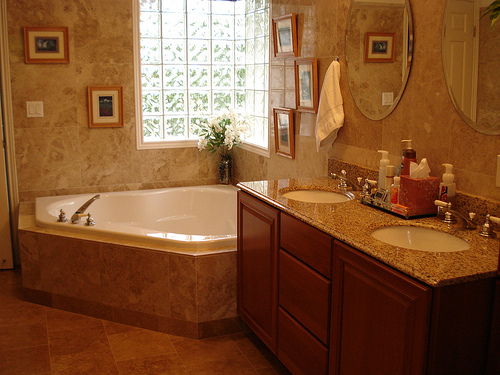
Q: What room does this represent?
A: It represents the bathroom.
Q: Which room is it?
A: It is a bathroom.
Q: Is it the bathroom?
A: Yes, it is the bathroom.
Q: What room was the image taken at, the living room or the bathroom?
A: It was taken at the bathroom.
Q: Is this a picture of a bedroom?
A: No, the picture is showing a bathroom.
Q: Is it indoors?
A: Yes, it is indoors.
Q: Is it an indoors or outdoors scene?
A: It is indoors.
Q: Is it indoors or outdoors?
A: It is indoors.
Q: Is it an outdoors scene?
A: No, it is indoors.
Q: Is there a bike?
A: No, there are no bikes.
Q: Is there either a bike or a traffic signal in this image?
A: No, there are no bikes or traffic lights.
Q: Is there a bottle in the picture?
A: Yes, there is a bottle.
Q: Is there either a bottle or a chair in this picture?
A: Yes, there is a bottle.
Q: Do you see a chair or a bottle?
A: Yes, there is a bottle.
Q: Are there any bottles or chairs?
A: Yes, there is a bottle.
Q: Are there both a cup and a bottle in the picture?
A: No, there is a bottle but no cups.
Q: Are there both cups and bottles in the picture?
A: No, there is a bottle but no cups.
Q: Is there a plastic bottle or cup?
A: Yes, there is a plastic bottle.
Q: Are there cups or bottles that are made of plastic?
A: Yes, the bottle is made of plastic.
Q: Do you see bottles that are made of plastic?
A: Yes, there is a bottle that is made of plastic.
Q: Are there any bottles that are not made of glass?
A: Yes, there is a bottle that is made of plastic.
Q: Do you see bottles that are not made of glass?
A: Yes, there is a bottle that is made of plastic.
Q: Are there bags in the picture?
A: No, there are no bags.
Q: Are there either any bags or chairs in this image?
A: No, there are no bags or chairs.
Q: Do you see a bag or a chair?
A: No, there are no bags or chairs.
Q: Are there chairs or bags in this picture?
A: No, there are no bags or chairs.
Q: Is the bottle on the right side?
A: Yes, the bottle is on the right of the image.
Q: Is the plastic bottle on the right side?
A: Yes, the bottle is on the right of the image.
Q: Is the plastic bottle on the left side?
A: No, the bottle is on the right of the image.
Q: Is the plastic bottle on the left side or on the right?
A: The bottle is on the right of the image.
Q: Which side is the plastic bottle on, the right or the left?
A: The bottle is on the right of the image.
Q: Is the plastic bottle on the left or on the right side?
A: The bottle is on the right of the image.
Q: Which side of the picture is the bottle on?
A: The bottle is on the right of the image.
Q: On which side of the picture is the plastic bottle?
A: The bottle is on the right of the image.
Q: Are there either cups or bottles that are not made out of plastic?
A: No, there is a bottle but it is made of plastic.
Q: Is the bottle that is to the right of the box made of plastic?
A: Yes, the bottle is made of plastic.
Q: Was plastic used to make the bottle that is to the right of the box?
A: Yes, the bottle is made of plastic.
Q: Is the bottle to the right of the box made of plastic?
A: Yes, the bottle is made of plastic.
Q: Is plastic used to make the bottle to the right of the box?
A: Yes, the bottle is made of plastic.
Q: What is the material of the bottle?
A: The bottle is made of plastic.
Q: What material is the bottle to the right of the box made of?
A: The bottle is made of plastic.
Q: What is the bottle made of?
A: The bottle is made of plastic.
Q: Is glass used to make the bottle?
A: No, the bottle is made of plastic.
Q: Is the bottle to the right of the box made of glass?
A: No, the bottle is made of plastic.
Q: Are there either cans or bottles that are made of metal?
A: No, there is a bottle but it is made of plastic.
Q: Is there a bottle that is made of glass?
A: No, there is a bottle but it is made of plastic.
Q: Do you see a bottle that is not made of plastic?
A: No, there is a bottle but it is made of plastic.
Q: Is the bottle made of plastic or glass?
A: The bottle is made of plastic.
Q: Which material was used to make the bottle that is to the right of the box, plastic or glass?
A: The bottle is made of plastic.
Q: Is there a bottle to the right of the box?
A: Yes, there is a bottle to the right of the box.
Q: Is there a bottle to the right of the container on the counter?
A: Yes, there is a bottle to the right of the box.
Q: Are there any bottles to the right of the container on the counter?
A: Yes, there is a bottle to the right of the box.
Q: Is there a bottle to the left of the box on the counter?
A: No, the bottle is to the right of the box.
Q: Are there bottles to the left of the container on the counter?
A: No, the bottle is to the right of the box.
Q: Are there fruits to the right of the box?
A: No, there is a bottle to the right of the box.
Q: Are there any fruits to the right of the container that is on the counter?
A: No, there is a bottle to the right of the box.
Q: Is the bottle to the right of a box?
A: Yes, the bottle is to the right of a box.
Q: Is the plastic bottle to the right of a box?
A: Yes, the bottle is to the right of a box.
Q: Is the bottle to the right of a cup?
A: No, the bottle is to the right of a box.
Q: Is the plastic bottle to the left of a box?
A: No, the bottle is to the right of a box.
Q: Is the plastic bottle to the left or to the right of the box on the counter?
A: The bottle is to the right of the box.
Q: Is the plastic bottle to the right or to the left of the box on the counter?
A: The bottle is to the right of the box.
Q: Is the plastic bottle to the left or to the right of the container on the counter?
A: The bottle is to the right of the box.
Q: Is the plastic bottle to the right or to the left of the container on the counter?
A: The bottle is to the right of the box.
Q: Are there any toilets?
A: No, there are no toilets.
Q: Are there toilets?
A: No, there are no toilets.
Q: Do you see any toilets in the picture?
A: No, there are no toilets.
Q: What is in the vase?
A: The flowers are in the vase.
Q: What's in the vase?
A: The flowers are in the vase.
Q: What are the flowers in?
A: The flowers are in the vase.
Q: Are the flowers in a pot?
A: No, the flowers are in the vase.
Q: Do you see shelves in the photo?
A: No, there are no shelves.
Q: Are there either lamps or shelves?
A: No, there are no shelves or lamps.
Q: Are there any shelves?
A: No, there are no shelves.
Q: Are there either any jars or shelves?
A: No, there are no shelves or jars.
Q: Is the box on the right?
A: Yes, the box is on the right of the image.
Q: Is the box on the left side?
A: No, the box is on the right of the image.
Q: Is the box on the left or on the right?
A: The box is on the right of the image.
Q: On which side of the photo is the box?
A: The box is on the right of the image.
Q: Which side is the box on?
A: The box is on the right of the image.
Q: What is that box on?
A: The box is on the counter.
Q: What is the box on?
A: The box is on the counter.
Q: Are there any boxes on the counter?
A: Yes, there is a box on the counter.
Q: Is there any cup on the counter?
A: No, there is a box on the counter.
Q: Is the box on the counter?
A: Yes, the box is on the counter.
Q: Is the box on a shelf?
A: No, the box is on the counter.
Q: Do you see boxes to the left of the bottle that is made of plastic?
A: Yes, there is a box to the left of the bottle.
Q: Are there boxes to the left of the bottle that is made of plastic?
A: Yes, there is a box to the left of the bottle.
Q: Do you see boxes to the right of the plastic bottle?
A: No, the box is to the left of the bottle.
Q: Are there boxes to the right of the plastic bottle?
A: No, the box is to the left of the bottle.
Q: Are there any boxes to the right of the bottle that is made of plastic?
A: No, the box is to the left of the bottle.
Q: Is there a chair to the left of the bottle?
A: No, there is a box to the left of the bottle.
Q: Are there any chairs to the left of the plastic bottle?
A: No, there is a box to the left of the bottle.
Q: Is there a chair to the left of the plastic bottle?
A: No, there is a box to the left of the bottle.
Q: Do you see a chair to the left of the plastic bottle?
A: No, there is a box to the left of the bottle.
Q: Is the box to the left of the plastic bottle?
A: Yes, the box is to the left of the bottle.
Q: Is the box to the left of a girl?
A: No, the box is to the left of the bottle.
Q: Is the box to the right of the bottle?
A: No, the box is to the left of the bottle.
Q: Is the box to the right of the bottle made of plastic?
A: No, the box is to the left of the bottle.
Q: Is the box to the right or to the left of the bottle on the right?
A: The box is to the left of the bottle.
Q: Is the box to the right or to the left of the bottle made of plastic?
A: The box is to the left of the bottle.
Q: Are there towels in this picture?
A: Yes, there is a towel.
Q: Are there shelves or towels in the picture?
A: Yes, there is a towel.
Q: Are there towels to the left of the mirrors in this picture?
A: Yes, there is a towel to the left of the mirrors.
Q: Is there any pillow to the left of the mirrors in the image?
A: No, there is a towel to the left of the mirrors.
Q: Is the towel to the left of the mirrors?
A: Yes, the towel is to the left of the mirrors.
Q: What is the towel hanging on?
A: The towel is hanging on the wall.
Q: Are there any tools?
A: No, there are no tools.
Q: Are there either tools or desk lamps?
A: No, there are no tools or desk lamps.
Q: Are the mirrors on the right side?
A: Yes, the mirrors are on the right of the image.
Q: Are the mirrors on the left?
A: No, the mirrors are on the right of the image.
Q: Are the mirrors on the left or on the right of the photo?
A: The mirrors are on the right of the image.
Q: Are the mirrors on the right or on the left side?
A: The mirrors are on the right of the image.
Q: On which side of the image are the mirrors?
A: The mirrors are on the right of the image.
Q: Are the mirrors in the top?
A: Yes, the mirrors are in the top of the image.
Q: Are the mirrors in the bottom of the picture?
A: No, the mirrors are in the top of the image.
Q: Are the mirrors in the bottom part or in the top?
A: The mirrors are in the top of the image.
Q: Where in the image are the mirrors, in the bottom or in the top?
A: The mirrors are in the top of the image.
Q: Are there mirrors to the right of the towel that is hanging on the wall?
A: Yes, there are mirrors to the right of the towel.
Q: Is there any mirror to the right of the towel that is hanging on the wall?
A: Yes, there are mirrors to the right of the towel.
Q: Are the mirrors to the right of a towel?
A: Yes, the mirrors are to the right of a towel.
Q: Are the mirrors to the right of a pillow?
A: No, the mirrors are to the right of a towel.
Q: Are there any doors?
A: Yes, there is a door.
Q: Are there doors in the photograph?
A: Yes, there is a door.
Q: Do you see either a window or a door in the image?
A: Yes, there is a door.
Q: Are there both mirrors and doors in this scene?
A: Yes, there are both a door and a mirror.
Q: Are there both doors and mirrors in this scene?
A: Yes, there are both a door and a mirror.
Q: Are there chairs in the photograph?
A: No, there are no chairs.